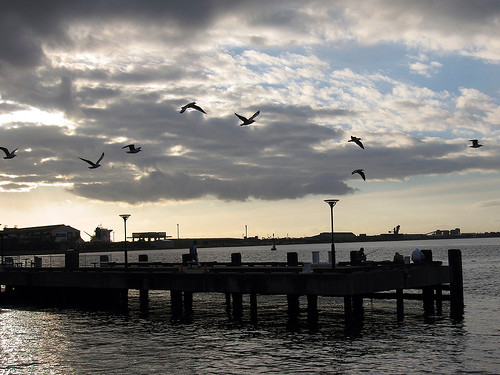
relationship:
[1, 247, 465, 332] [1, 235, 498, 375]
dock in water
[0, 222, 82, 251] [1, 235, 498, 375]
building behind water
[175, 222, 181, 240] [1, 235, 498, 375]
light pole by water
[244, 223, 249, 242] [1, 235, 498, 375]
right light pole by water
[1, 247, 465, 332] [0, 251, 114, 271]
dock has railing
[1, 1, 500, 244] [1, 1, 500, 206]
sky has clouds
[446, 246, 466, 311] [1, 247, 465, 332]
final piling of dock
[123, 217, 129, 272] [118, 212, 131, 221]
post has lamp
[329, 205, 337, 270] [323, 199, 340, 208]
right post has right lamp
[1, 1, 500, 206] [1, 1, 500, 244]
clouds in sky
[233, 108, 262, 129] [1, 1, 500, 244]
bird in sky